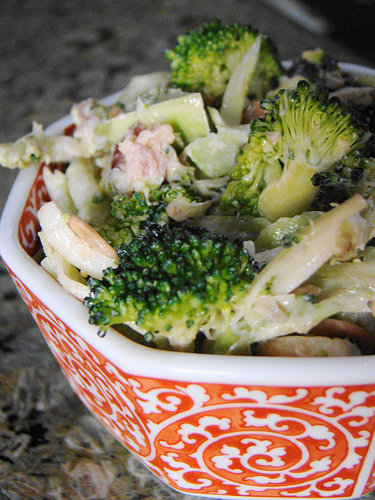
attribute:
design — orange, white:
[162, 384, 362, 493]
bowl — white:
[63, 303, 357, 461]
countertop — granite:
[0, 0, 368, 500]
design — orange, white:
[68, 355, 346, 464]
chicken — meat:
[117, 125, 177, 181]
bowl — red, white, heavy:
[1, 59, 373, 497]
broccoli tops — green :
[82, 216, 247, 343]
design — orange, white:
[17, 196, 39, 247]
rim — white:
[6, 58, 374, 384]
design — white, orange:
[121, 380, 356, 488]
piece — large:
[81, 222, 267, 354]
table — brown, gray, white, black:
[1, 3, 373, 498]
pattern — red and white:
[6, 168, 372, 497]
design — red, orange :
[29, 304, 372, 496]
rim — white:
[118, 353, 373, 387]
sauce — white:
[0, 47, 375, 355]